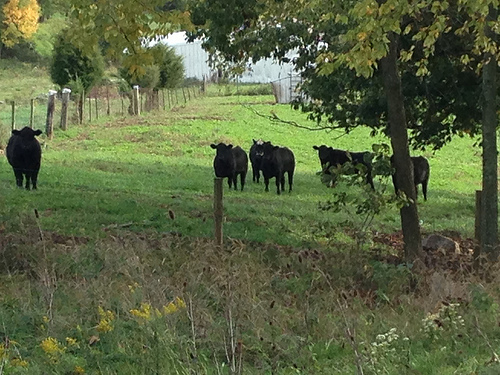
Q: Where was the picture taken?
A: It was taken at the field.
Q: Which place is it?
A: It is a field.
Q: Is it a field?
A: Yes, it is a field.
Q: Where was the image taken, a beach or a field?
A: It was taken at a field.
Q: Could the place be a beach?
A: No, it is a field.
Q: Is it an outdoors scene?
A: Yes, it is outdoors.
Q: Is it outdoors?
A: Yes, it is outdoors.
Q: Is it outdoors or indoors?
A: It is outdoors.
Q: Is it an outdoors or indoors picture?
A: It is outdoors.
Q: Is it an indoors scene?
A: No, it is outdoors.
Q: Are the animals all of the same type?
A: Yes, all the animals are cows.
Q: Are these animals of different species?
A: No, all the animals are cows.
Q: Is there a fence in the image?
A: Yes, there is a fence.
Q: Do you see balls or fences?
A: Yes, there is a fence.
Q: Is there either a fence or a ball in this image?
A: Yes, there is a fence.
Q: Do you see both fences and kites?
A: No, there is a fence but no kites.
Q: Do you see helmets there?
A: No, there are no helmets.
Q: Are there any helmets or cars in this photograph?
A: No, there are no helmets or cars.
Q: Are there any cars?
A: No, there are no cars.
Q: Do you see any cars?
A: No, there are no cars.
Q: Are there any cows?
A: Yes, there are cows.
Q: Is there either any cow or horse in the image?
A: Yes, there are cows.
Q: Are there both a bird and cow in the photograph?
A: No, there are cows but no birds.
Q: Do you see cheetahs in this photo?
A: No, there are no cheetahs.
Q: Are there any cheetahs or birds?
A: No, there are no cheetahs or birds.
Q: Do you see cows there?
A: Yes, there are cows.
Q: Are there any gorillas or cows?
A: Yes, there are cows.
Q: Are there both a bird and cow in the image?
A: No, there are cows but no birds.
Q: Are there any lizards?
A: No, there are no lizards.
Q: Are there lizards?
A: No, there are no lizards.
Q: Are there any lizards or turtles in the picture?
A: No, there are no lizards or turtles.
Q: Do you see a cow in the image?
A: Yes, there are cows.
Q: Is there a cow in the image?
A: Yes, there are cows.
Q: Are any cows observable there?
A: Yes, there are cows.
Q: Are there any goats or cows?
A: Yes, there are cows.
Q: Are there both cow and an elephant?
A: No, there are cows but no elephants.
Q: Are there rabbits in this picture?
A: No, there are no rabbits.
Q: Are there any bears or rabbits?
A: No, there are no rabbits or bears.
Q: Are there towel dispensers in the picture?
A: No, there are no towel dispensers.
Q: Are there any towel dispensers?
A: No, there are no towel dispensers.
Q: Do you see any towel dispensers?
A: No, there are no towel dispensers.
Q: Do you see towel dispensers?
A: No, there are no towel dispensers.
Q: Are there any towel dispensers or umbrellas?
A: No, there are no towel dispensers or umbrellas.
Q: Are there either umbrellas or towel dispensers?
A: No, there are no towel dispensers or umbrellas.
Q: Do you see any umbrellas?
A: No, there are no umbrellas.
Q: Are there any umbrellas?
A: No, there are no umbrellas.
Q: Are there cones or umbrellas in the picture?
A: No, there are no umbrellas or cones.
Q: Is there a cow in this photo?
A: Yes, there is a cow.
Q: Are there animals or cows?
A: Yes, there is a cow.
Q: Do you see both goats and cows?
A: No, there is a cow but no goats.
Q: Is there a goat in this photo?
A: No, there are no goats.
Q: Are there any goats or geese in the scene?
A: No, there are no goats or geese.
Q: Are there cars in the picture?
A: No, there are no cars.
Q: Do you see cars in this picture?
A: No, there are no cars.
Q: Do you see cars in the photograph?
A: No, there are no cars.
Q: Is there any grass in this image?
A: Yes, there is grass.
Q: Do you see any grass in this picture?
A: Yes, there is grass.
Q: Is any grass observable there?
A: Yes, there is grass.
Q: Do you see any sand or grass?
A: Yes, there is grass.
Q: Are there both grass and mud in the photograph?
A: No, there is grass but no mud.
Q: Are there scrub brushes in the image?
A: No, there are no scrub brushes.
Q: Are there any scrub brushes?
A: No, there are no scrub brushes.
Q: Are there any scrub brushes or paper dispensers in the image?
A: No, there are no scrub brushes or paper dispensers.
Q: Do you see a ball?
A: No, there are no balls.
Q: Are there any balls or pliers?
A: No, there are no balls or pliers.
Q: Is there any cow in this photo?
A: Yes, there is a cow.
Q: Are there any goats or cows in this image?
A: Yes, there is a cow.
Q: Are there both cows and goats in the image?
A: No, there is a cow but no goats.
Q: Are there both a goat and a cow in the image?
A: No, there is a cow but no goats.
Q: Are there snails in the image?
A: No, there are no snails.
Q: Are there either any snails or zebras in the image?
A: No, there are no snails or zebras.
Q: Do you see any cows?
A: Yes, there are cows.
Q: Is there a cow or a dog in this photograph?
A: Yes, there are cows.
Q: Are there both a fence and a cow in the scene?
A: Yes, there are both a cow and a fence.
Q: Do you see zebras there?
A: No, there are no zebras.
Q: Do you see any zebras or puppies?
A: No, there are no zebras or puppies.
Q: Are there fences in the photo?
A: Yes, there is a fence.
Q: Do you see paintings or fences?
A: Yes, there is a fence.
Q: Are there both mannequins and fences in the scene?
A: No, there is a fence but no mannequins.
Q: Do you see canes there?
A: No, there are no canes.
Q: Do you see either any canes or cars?
A: No, there are no canes or cars.